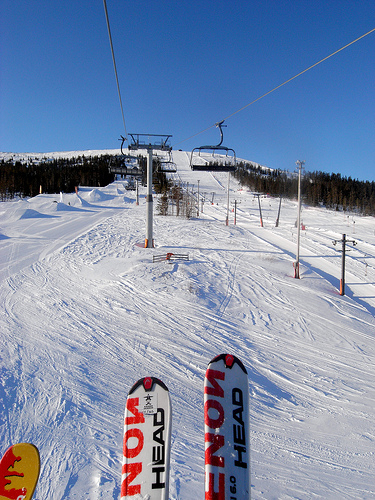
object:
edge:
[152, 402, 168, 492]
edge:
[231, 386, 249, 469]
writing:
[122, 392, 171, 490]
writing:
[212, 357, 249, 483]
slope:
[15, 160, 343, 467]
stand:
[3, 151, 163, 200]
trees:
[223, 165, 363, 207]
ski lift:
[109, 133, 143, 178]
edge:
[0, 436, 49, 500]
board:
[202, 352, 252, 500]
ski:
[119, 375, 172, 500]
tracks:
[28, 219, 283, 414]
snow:
[10, 184, 357, 487]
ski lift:
[188, 117, 241, 174]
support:
[119, 130, 183, 249]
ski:
[1, 435, 54, 498]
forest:
[222, 160, 375, 216]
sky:
[6, 11, 363, 153]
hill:
[87, 186, 110, 198]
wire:
[182, 29, 363, 149]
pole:
[295, 160, 305, 276]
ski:
[203, 351, 250, 497]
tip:
[207, 353, 247, 374]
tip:
[127, 376, 168, 393]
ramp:
[83, 187, 112, 204]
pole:
[144, 147, 155, 247]